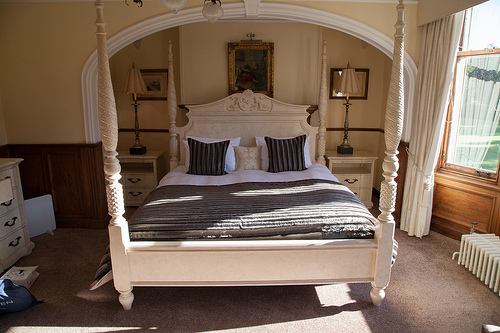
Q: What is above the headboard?
A: Painting.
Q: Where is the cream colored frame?
A: Around the bed.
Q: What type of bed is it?
A: Four poster.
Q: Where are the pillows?
A: Stacked on a bed.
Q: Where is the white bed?
A: In the room.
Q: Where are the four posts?
A: On the bed.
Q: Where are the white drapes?
A: On the window.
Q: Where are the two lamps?
A: Beside the bed.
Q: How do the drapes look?
A: Open.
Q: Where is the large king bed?
A: In the bedroom.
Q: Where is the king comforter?
A: Covering the mattress.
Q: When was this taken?
A: In the daytime hours.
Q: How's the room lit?
A: With sunlight through the windows.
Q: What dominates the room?
A: A large four poster wooden bed.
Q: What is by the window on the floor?
A: A radiator.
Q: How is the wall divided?
A: With wood paneling below and paint above.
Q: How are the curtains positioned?
A: Open.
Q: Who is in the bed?
A: No one.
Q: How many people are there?
A: None.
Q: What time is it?
A: Daytime.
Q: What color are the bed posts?
A: White.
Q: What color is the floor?
A: Gray.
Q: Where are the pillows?
A: On the bed.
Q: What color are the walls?
A: Tan.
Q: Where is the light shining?
A: Through the windows.